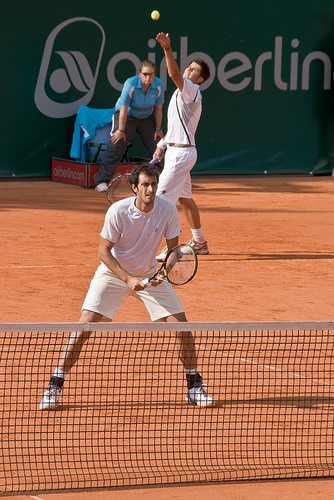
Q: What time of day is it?
A: Daytime.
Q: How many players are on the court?
A: Two.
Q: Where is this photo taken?
A: On a tennis court.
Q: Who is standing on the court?
A: Men.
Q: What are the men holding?
A: Tennis rackets.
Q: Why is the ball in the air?
A: Because the player threw it into the air.